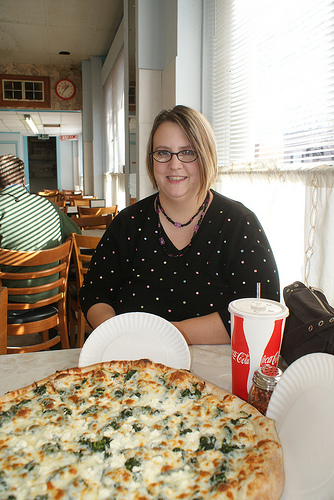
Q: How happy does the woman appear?
A: Somewhat happy.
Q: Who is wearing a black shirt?
A: The woman behind the pizza.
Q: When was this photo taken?
A: During daylight hours.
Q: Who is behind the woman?
A: A man.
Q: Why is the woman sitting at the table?
A: Getting ready to eat.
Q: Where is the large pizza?
A: On the table.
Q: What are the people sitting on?
A: Chairs.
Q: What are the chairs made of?
A: Wood.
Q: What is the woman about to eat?
A: Pizza.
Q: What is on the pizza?
A: Cheese and spinach.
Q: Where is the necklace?
A: Around the woman's neck.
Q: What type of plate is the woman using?
A: A paper plate.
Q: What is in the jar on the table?
A: Red pepper flakes.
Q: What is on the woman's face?
A: Eyeglasses.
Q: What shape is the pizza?
A: Round.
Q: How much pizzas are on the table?
A: One.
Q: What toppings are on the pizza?
A: Spinach and cheese.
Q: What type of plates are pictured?
A: Paper plates.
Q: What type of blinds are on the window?
A: Mini blinds.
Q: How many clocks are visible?
A: 1.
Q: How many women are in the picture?
A: 1.